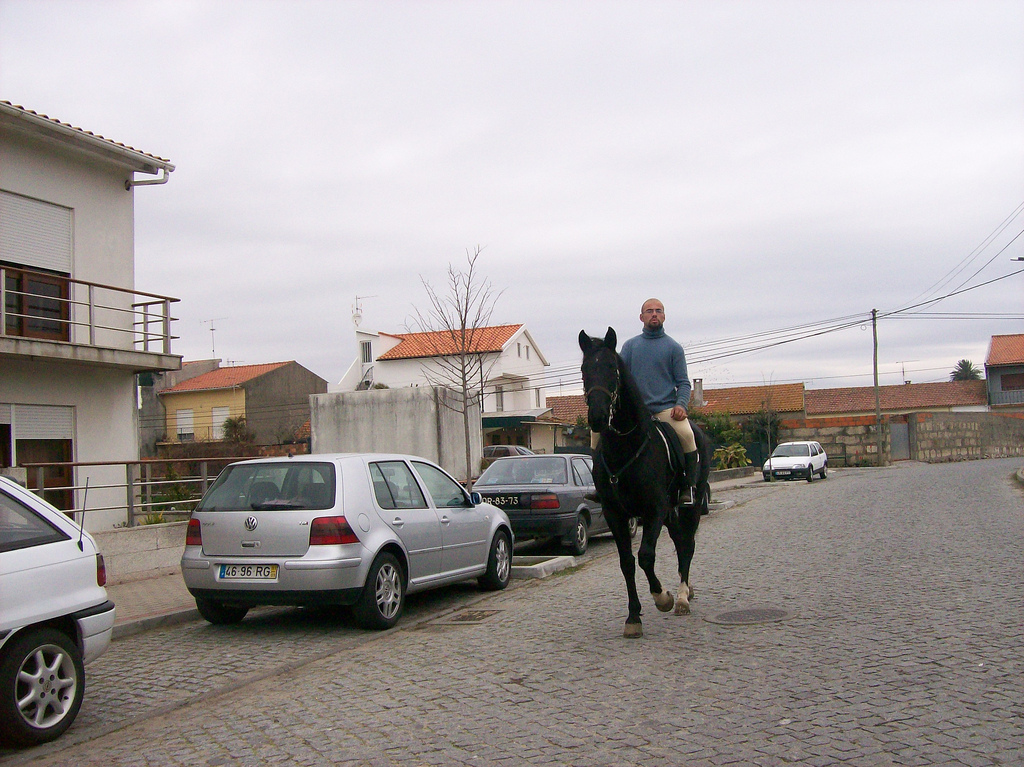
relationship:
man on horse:
[620, 295, 700, 514] [578, 326, 710, 638]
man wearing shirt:
[620, 295, 700, 514] [619, 328, 691, 415]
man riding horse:
[583, 299, 698, 508] [578, 326, 710, 638]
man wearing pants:
[583, 299, 698, 508] [643, 403, 698, 452]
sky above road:
[4, 5, 1022, 391] [29, 446, 1022, 756]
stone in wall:
[807, 432, 824, 453] [807, 432, 824, 453]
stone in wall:
[814, 413, 857, 445] [811, 416, 841, 437]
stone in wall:
[781, 422, 810, 441] [781, 422, 810, 441]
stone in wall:
[842, 438, 868, 462] [842, 438, 868, 462]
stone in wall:
[934, 442, 941, 466] [934, 442, 941, 466]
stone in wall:
[905, 420, 929, 455] [914, 432, 930, 451]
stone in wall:
[915, 428, 941, 439] [906, 423, 944, 444]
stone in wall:
[940, 420, 959, 437] [940, 420, 959, 437]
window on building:
[204, 397, 233, 437] [155, 361, 331, 463]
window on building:
[177, 401, 203, 437] [155, 361, 331, 463]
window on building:
[11, 400, 119, 541] [1, 110, 181, 527]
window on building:
[513, 333, 526, 354] [343, 324, 558, 456]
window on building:
[520, 334, 544, 358] [343, 324, 558, 456]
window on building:
[531, 371, 563, 406] [343, 324, 558, 456]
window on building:
[490, 379, 510, 412] [343, 324, 558, 456]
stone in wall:
[818, 426, 846, 435] [782, 406, 1022, 469]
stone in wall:
[851, 435, 880, 455] [782, 406, 1022, 469]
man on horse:
[583, 299, 698, 508] [572, 320, 715, 640]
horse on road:
[482, 230, 781, 663] [95, 454, 1023, 756]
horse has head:
[578, 326, 710, 638] [560, 336, 633, 428]